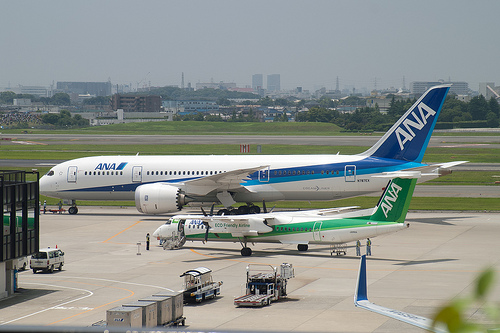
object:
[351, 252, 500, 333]
wing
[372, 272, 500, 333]
corner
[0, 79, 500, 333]
airport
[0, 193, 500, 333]
tarmac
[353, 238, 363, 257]
person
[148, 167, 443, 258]
plane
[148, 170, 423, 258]
airline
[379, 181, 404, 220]
ana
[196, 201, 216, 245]
propellers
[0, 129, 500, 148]
runway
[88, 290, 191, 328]
cargo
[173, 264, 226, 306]
tram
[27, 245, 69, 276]
van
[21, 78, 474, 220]
plane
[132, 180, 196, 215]
engine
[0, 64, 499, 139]
city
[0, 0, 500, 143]
background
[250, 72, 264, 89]
high rise building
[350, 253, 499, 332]
airplane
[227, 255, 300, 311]
luggage cart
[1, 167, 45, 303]
building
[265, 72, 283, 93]
tall skyscraper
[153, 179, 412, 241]
green strip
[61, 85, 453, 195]
blue strip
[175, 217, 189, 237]
door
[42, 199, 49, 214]
person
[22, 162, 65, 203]
nose of plane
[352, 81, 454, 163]
airplane rudder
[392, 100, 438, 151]
ana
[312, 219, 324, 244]
emergency exit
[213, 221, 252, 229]
eco friendly wording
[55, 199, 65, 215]
person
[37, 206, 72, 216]
luggage cart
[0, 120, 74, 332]
terminal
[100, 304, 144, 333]
luggage carts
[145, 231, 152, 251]
person